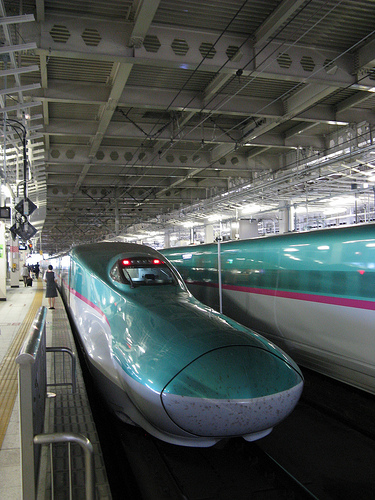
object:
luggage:
[27, 278, 33, 287]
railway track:
[150, 447, 318, 500]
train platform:
[0, 272, 108, 498]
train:
[159, 222, 373, 374]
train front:
[160, 341, 310, 447]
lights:
[242, 205, 262, 216]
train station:
[2, 0, 373, 499]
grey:
[312, 311, 369, 346]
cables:
[149, 1, 249, 136]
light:
[154, 259, 160, 264]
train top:
[69, 240, 308, 400]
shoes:
[52, 306, 56, 310]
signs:
[15, 197, 38, 217]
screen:
[120, 258, 166, 268]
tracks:
[254, 440, 330, 497]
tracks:
[138, 432, 202, 498]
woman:
[43, 265, 58, 310]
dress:
[43, 269, 59, 297]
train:
[37, 240, 305, 448]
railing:
[44, 345, 77, 395]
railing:
[33, 431, 98, 497]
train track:
[105, 428, 323, 498]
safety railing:
[17, 307, 95, 492]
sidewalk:
[0, 270, 110, 499]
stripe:
[187, 277, 374, 326]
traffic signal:
[25, 238, 33, 250]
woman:
[21, 264, 29, 287]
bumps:
[0, 278, 44, 445]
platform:
[2, 269, 113, 500]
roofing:
[0, 16, 350, 250]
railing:
[32, 342, 96, 500]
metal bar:
[52, 351, 57, 384]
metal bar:
[47, 443, 56, 500]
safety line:
[20, 278, 47, 341]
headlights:
[122, 259, 129, 265]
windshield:
[122, 265, 175, 284]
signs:
[15, 219, 38, 240]